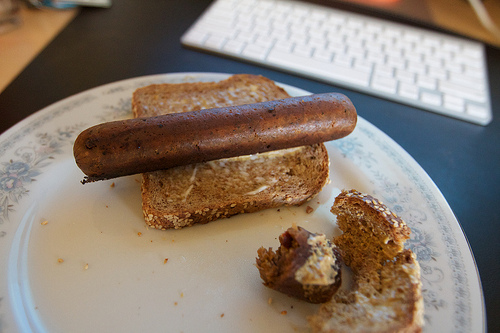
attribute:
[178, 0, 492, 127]
keyboard — white, wireless, blurry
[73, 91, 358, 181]
hot dog — brown, cooked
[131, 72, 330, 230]
toast — brown, wheat bread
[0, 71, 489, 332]
plate — white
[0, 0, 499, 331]
mat — black, blue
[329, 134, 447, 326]
design — blue, flowery, floral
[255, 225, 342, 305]
hot dog — almost finished, mostly eaten, sandwich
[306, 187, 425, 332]
bread — almost finished, wheat, half eaten, mostly eaten, brown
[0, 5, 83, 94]
border — brown